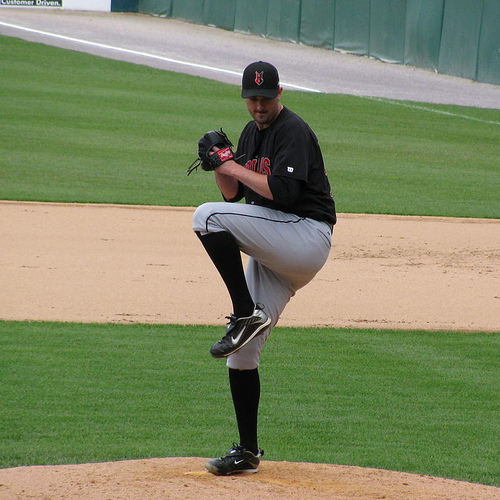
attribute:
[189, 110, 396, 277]
shirt — black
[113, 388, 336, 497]
mound — tan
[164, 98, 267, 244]
glove — black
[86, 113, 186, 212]
grass — green, mowed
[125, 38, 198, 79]
line — white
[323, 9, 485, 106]
wall — green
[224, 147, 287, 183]
logo — nike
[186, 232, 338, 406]
cleat — black, hwite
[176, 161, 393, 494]
pants — gray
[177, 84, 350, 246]
jersey — black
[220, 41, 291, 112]
cap — black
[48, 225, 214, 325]
ground — brown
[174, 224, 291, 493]
sock — black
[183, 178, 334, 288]
stripe — black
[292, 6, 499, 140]
walls — green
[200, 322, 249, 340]
lace — black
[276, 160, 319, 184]
emblem — white